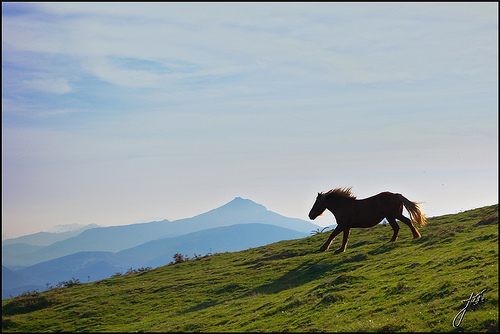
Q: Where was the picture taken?
A: It was taken at the field.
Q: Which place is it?
A: It is a field.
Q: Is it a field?
A: Yes, it is a field.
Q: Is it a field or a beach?
A: It is a field.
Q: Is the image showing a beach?
A: No, the picture is showing a field.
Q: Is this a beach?
A: No, it is a field.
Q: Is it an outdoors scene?
A: Yes, it is outdoors.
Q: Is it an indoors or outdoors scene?
A: It is outdoors.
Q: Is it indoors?
A: No, it is outdoors.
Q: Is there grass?
A: Yes, there is grass.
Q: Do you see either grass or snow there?
A: Yes, there is grass.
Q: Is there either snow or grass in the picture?
A: Yes, there is grass.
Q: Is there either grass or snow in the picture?
A: Yes, there is grass.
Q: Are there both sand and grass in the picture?
A: No, there is grass but no sand.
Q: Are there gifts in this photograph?
A: No, there are no gifts.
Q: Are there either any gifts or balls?
A: No, there are no gifts or balls.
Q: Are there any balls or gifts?
A: No, there are no gifts or balls.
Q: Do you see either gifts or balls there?
A: No, there are no gifts or balls.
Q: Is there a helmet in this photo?
A: No, there are no helmets.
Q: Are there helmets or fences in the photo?
A: No, there are no helmets or fences.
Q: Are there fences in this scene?
A: No, there are no fences.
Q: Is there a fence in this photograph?
A: No, there are no fences.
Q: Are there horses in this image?
A: Yes, there is a horse.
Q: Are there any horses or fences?
A: Yes, there is a horse.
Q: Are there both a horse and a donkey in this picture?
A: No, there is a horse but no donkeys.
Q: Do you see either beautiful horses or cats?
A: Yes, there is a beautiful horse.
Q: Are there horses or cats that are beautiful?
A: Yes, the horse is beautiful.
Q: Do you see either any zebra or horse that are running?
A: Yes, the horse is running.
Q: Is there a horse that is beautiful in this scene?
A: Yes, there is a beautiful horse.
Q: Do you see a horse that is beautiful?
A: Yes, there is a horse that is beautiful.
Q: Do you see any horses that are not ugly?
A: Yes, there is an beautiful horse.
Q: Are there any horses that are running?
A: Yes, there is a horse that is running.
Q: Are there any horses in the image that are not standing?
A: Yes, there is a horse that is running.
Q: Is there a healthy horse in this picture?
A: Yes, there is a healthy horse.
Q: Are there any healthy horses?
A: Yes, there is a healthy horse.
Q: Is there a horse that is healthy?
A: Yes, there is a horse that is healthy.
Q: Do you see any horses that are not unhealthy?
A: Yes, there is an healthy horse.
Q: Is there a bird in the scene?
A: No, there are no birds.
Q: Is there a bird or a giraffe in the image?
A: No, there are no birds or giraffes.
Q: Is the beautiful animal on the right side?
A: Yes, the horse is on the right of the image.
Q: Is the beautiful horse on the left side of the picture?
A: No, the horse is on the right of the image.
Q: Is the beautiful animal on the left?
A: No, the horse is on the right of the image.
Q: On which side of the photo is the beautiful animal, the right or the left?
A: The horse is on the right of the image.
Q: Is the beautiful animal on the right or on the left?
A: The horse is on the right of the image.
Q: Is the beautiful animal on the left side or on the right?
A: The horse is on the right of the image.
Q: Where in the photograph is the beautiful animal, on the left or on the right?
A: The horse is on the right of the image.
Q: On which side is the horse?
A: The horse is on the right of the image.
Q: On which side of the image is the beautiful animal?
A: The horse is on the right of the image.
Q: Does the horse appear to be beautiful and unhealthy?
A: No, the horse is beautiful but healthy.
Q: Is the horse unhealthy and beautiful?
A: No, the horse is beautiful but healthy.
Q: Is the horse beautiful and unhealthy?
A: No, the horse is beautiful but healthy.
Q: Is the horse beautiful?
A: Yes, the horse is beautiful.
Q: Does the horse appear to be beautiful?
A: Yes, the horse is beautiful.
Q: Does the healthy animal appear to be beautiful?
A: Yes, the horse is beautiful.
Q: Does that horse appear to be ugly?
A: No, the horse is beautiful.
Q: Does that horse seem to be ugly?
A: No, the horse is beautiful.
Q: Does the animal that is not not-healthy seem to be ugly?
A: No, the horse is beautiful.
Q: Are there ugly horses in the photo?
A: No, there is a horse but it is beautiful.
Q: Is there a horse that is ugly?
A: No, there is a horse but it is beautiful.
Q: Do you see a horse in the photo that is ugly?
A: No, there is a horse but it is beautiful.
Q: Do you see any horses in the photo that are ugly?
A: No, there is a horse but it is beautiful.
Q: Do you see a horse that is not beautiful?
A: No, there is a horse but it is beautiful.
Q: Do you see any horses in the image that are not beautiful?
A: No, there is a horse but it is beautiful.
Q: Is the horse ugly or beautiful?
A: The horse is beautiful.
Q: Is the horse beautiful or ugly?
A: The horse is beautiful.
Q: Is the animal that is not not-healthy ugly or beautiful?
A: The horse is beautiful.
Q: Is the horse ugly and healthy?
A: No, the horse is healthy but beautiful.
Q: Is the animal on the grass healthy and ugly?
A: No, the horse is healthy but beautiful.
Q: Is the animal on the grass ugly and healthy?
A: No, the horse is healthy but beautiful.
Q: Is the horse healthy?
A: Yes, the horse is healthy.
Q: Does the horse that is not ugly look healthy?
A: Yes, the horse is healthy.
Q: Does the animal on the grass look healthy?
A: Yes, the horse is healthy.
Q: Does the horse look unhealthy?
A: No, the horse is healthy.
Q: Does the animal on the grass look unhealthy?
A: No, the horse is healthy.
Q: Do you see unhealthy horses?
A: No, there is a horse but it is healthy.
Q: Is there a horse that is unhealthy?
A: No, there is a horse but it is healthy.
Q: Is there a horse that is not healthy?
A: No, there is a horse but it is healthy.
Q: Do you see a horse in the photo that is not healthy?
A: No, there is a horse but it is healthy.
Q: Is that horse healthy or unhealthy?
A: The horse is healthy.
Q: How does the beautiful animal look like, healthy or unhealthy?
A: The horse is healthy.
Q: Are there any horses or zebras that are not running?
A: No, there is a horse but it is running.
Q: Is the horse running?
A: Yes, the horse is running.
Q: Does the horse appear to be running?
A: Yes, the horse is running.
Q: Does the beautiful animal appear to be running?
A: Yes, the horse is running.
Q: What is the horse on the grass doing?
A: The horse is running.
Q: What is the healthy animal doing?
A: The horse is running.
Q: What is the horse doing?
A: The horse is running.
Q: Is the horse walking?
A: No, the horse is running.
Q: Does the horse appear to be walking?
A: No, the horse is running.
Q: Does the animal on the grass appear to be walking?
A: No, the horse is running.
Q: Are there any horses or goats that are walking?
A: No, there is a horse but it is running.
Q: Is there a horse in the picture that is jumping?
A: No, there is a horse but it is running.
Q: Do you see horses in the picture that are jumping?
A: No, there is a horse but it is running.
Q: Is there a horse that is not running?
A: No, there is a horse but it is running.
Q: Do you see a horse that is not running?
A: No, there is a horse but it is running.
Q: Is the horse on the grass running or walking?
A: The horse is running.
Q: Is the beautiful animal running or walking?
A: The horse is running.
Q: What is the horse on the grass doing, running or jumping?
A: The horse is running.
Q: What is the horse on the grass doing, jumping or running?
A: The horse is running.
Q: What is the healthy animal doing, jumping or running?
A: The horse is running.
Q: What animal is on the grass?
A: The animal is a horse.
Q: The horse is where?
A: The horse is on the grass.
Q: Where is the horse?
A: The horse is on the grass.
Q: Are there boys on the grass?
A: No, there is a horse on the grass.